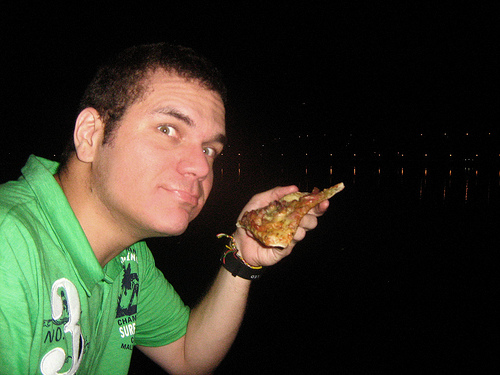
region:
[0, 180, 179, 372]
a man wearing a green shirt with white and black design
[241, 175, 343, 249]
a slice of pizza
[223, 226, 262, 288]
a man wearing wrist braclettes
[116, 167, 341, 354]
a man holding his hand up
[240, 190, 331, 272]
pizza in the hand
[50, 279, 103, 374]
the number is 3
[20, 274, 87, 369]
the number is white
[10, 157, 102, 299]
collar on the shirt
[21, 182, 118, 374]
the shirt is green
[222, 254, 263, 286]
watch on the wrist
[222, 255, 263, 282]
the watch is black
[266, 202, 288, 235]
toppings on the pizza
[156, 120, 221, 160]
the eyes are wide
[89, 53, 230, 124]
the hair is dark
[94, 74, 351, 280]
man holding a pizza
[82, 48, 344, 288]
man holding a pizza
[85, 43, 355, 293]
man holding a pizza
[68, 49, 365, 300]
man holding a pizza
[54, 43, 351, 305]
man holding a pizza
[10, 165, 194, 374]
the shirt is green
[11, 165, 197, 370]
the shirt is green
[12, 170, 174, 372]
the shirt is green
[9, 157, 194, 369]
the shirt is green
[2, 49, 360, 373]
Man holding slice of pizza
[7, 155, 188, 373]
green shirt man is wearing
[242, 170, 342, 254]
slice of pizza man is holding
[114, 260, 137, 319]
black logo on man's shirt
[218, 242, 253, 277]
black watchband on man's wrist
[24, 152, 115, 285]
collar on man's shirt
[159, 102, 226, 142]
eyebrows on the man's face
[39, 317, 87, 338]
black lettering on the shirt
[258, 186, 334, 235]
topping on the pizza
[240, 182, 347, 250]
Piece of pizza in a man's hand.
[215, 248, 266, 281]
Black watch band.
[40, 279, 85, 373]
Large white 3.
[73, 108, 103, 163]
Large fleshy ear.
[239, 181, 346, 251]
pizza is held by human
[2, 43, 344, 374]
human holds pizza in hand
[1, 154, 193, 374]
green shirt worn by human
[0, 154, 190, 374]
shirt is green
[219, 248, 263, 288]
wrist watch worn by human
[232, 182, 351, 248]
Slice of pizza with toppings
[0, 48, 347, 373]
Man holding a slice of pizza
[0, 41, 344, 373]
Man wearing a green shirt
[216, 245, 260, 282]
Black rubber bracelet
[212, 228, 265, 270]
Colorful string bracelet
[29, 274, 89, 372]
White number three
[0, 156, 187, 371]
Green polo shirt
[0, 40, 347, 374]
A man eating pizza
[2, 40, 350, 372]
A man with dark hair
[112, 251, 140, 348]
Blue and white writing on the shirt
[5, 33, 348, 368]
a man holding a piece of pizza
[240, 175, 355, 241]
a small piece of pizza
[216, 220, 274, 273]
a multi colored bracelet on a wrist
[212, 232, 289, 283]
a black watch on a wrist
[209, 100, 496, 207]
a row of lights in the background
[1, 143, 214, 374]
a green polo shirt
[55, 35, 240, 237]
a man with short hair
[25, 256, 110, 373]
a large number 3 on a shirt